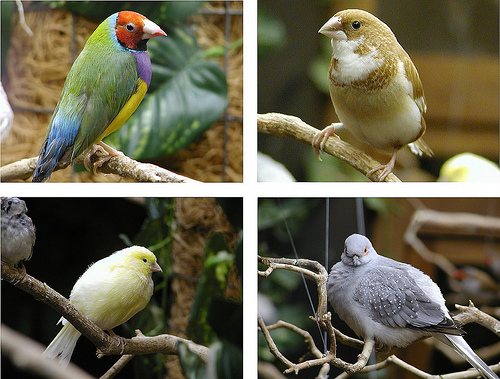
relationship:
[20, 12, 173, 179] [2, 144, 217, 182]
bird on a branch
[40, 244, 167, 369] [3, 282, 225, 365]
bird on a branch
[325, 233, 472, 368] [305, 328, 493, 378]
bird on a branch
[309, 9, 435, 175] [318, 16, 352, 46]
bird has a beak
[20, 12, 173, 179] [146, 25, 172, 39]
bird has a beak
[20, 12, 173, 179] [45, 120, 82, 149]
bird has feathers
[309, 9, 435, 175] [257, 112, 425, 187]
bird on a branch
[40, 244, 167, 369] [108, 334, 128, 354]
bird has claws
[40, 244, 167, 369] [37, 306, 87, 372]
bird has a tail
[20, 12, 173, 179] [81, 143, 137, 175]
bird has claws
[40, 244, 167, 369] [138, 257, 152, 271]
bird has an eye